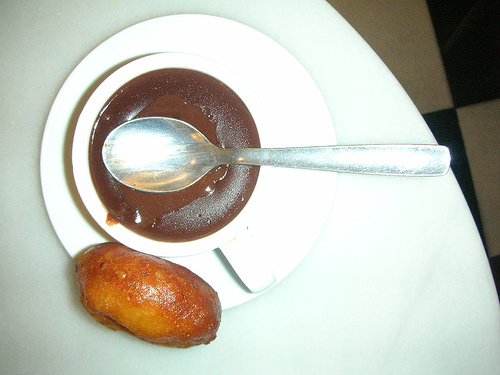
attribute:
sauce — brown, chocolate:
[194, 93, 223, 118]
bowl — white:
[125, 65, 148, 78]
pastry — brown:
[68, 242, 198, 329]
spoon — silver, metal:
[93, 102, 477, 188]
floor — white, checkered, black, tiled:
[428, 5, 469, 34]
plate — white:
[218, 22, 317, 60]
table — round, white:
[292, 16, 304, 18]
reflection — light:
[398, 154, 442, 171]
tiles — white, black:
[466, 136, 478, 141]